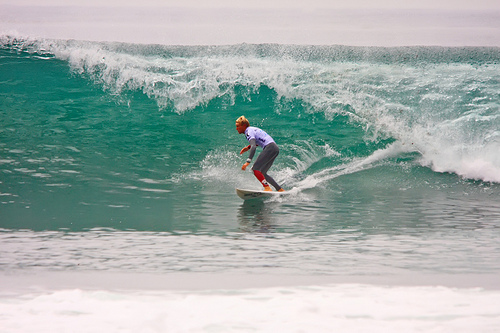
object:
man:
[234, 113, 286, 193]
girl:
[234, 114, 287, 192]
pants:
[249, 141, 282, 194]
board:
[233, 187, 284, 200]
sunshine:
[0, 0, 499, 333]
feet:
[261, 185, 273, 194]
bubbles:
[0, 31, 499, 196]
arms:
[245, 127, 259, 163]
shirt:
[243, 125, 278, 165]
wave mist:
[195, 137, 344, 195]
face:
[234, 121, 244, 136]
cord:
[251, 169, 271, 187]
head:
[232, 115, 250, 135]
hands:
[238, 161, 252, 172]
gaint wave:
[0, 29, 499, 204]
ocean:
[0, 2, 499, 333]